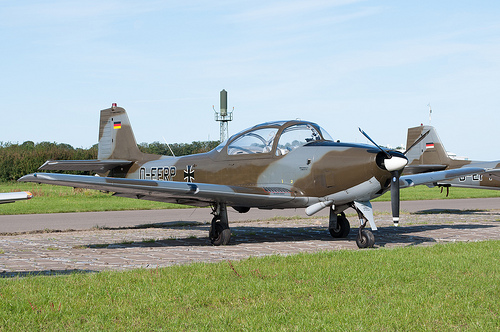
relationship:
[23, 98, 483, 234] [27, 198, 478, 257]
jet parked on runway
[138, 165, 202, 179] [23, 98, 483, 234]
logo painted on jet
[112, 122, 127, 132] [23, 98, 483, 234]
sticker stuck on jet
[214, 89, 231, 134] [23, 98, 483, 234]
tower behind jet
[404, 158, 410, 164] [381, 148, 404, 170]
tip of nose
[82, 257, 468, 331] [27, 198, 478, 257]
grass next to runway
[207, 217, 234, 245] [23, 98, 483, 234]
wheel under jet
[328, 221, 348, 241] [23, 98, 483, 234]
wheel under jet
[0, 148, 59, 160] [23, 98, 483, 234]
tree behind jet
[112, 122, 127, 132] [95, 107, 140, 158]
sticker stuck on tail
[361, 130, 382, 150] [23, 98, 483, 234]
propeller of jet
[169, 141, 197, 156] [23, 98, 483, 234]
tree behind jet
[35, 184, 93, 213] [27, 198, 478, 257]
grass next to runway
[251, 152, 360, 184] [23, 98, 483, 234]
paint painte on jet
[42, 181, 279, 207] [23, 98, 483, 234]
wing of jet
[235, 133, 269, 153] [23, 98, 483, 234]
window in jet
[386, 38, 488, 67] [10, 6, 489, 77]
cloud in sky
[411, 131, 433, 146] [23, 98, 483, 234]
propeller on jet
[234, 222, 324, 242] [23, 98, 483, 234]
shadow under jet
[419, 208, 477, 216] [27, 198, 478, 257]
shadow on runway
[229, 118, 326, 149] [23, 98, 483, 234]
cockpit of jet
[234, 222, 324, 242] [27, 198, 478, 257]
shadow on runway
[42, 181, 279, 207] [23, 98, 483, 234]
wing on jet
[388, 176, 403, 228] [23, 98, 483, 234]
propeller on jet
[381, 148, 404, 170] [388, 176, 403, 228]
nose attached to propeller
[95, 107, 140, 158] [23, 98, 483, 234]
tail of jet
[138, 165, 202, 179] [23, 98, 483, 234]
logo on jet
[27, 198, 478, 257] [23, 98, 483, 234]
runway under jet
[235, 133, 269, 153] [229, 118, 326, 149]
window of cockpit